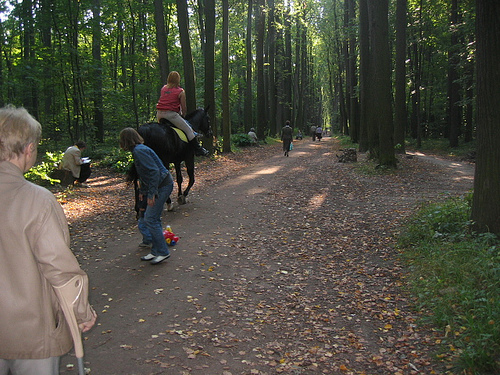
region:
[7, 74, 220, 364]
people on path in the woods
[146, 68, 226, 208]
girl riding a horse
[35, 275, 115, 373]
crutch on a woman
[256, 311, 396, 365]
leaves on the ground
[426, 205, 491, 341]
green grass by the tree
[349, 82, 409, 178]
trunks of a tree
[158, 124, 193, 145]
saddle on a horse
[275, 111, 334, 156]
people in the woods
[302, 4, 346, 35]
light shining through the trees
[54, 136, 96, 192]
woman sitting on a log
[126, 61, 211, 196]
person riding horse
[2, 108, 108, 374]
person wearing light brown coat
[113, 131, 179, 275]
person wearing blue jeans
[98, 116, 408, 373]
leaves scattered on path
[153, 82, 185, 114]
red shirt of person on horse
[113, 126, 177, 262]
person standing behind horse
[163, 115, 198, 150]
saddle on horse's back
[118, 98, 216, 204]
horse being ridden by woman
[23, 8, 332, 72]
sunlight coming through the trees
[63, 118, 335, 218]
sunlight on pathway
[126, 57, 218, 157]
a woman riding a horse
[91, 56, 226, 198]
a woman riding a horse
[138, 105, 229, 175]
the horse is black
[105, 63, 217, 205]
the horse is black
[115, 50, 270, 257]
the horse is black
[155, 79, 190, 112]
A woman with red top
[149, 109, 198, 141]
Gray pants in the photo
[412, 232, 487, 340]
Green plants on the roadside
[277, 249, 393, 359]
Dry leaves in the photo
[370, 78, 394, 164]
Tree trunk in the photo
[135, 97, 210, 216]
A black horse on the path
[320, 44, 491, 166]
A forest in the picture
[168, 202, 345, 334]
A dirt road in the photo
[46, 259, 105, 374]
Clutches in the photo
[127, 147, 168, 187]
Blue jacket in the photo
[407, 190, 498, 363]
a section of green grass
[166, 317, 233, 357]
brown leaves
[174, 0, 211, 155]
a tall tree branch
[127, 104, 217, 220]
a large black horse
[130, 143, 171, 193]
a woman's blue shirt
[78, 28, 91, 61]
green tree leaves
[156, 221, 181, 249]
different types of colorful balloons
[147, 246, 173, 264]
the shoe of a woman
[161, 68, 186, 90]
a woman's blonde hair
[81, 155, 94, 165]
white pieces of paper